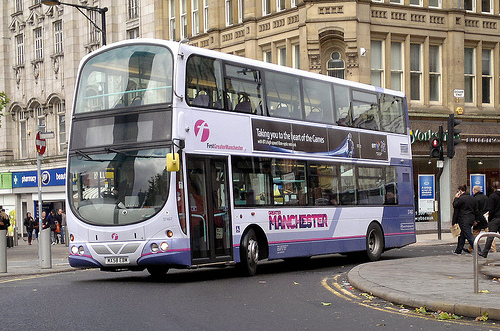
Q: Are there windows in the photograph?
A: Yes, there is a window.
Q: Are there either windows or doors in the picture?
A: Yes, there is a window.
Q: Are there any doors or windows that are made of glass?
A: Yes, the window is made of glass.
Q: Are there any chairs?
A: No, there are no chairs.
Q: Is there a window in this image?
A: Yes, there is a window.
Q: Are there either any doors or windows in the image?
A: Yes, there is a window.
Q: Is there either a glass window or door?
A: Yes, there is a glass window.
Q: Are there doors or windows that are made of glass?
A: Yes, the window is made of glass.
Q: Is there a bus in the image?
A: Yes, there is a bus.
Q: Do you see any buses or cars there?
A: Yes, there is a bus.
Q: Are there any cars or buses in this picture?
A: Yes, there is a bus.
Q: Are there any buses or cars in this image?
A: Yes, there is a bus.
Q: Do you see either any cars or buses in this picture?
A: Yes, there is a bus.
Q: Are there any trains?
A: No, there are no trains.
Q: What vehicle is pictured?
A: The vehicle is a bus.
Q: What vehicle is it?
A: The vehicle is a bus.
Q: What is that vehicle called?
A: This is a bus.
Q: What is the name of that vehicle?
A: This is a bus.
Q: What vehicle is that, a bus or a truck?
A: This is a bus.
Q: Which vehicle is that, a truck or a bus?
A: This is a bus.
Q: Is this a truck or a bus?
A: This is a bus.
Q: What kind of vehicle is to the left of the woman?
A: The vehicle is a bus.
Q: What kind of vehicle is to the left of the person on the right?
A: The vehicle is a bus.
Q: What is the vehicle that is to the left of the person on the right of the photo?
A: The vehicle is a bus.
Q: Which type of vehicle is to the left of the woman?
A: The vehicle is a bus.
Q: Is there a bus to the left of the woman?
A: Yes, there is a bus to the left of the woman.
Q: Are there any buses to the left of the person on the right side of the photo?
A: Yes, there is a bus to the left of the woman.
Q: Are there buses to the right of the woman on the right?
A: No, the bus is to the left of the woman.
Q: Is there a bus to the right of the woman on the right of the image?
A: No, the bus is to the left of the woman.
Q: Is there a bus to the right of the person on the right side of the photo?
A: No, the bus is to the left of the woman.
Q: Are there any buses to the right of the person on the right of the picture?
A: No, the bus is to the left of the woman.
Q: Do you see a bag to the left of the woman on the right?
A: No, there is a bus to the left of the woman.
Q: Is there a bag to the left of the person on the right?
A: No, there is a bus to the left of the woman.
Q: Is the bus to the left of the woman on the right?
A: Yes, the bus is to the left of the woman.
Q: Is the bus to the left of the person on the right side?
A: Yes, the bus is to the left of the woman.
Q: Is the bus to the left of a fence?
A: No, the bus is to the left of the woman.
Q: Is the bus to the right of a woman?
A: No, the bus is to the left of a woman.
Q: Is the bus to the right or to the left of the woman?
A: The bus is to the left of the woman.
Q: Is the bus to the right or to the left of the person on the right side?
A: The bus is to the left of the woman.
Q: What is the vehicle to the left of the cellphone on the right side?
A: The vehicle is a bus.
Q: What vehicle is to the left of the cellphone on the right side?
A: The vehicle is a bus.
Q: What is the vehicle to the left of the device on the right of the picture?
A: The vehicle is a bus.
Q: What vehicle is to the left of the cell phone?
A: The vehicle is a bus.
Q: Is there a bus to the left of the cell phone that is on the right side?
A: Yes, there is a bus to the left of the cell phone.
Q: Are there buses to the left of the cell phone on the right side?
A: Yes, there is a bus to the left of the cell phone.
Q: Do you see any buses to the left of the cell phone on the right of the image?
A: Yes, there is a bus to the left of the cell phone.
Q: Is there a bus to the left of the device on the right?
A: Yes, there is a bus to the left of the cell phone.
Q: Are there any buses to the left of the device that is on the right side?
A: Yes, there is a bus to the left of the cell phone.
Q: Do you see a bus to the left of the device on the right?
A: Yes, there is a bus to the left of the cell phone.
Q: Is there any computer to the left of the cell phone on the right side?
A: No, there is a bus to the left of the cellphone.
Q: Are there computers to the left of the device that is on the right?
A: No, there is a bus to the left of the cellphone.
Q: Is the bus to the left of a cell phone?
A: Yes, the bus is to the left of a cell phone.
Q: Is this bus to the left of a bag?
A: No, the bus is to the left of a cell phone.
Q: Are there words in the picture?
A: Yes, there are words.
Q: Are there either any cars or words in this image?
A: Yes, there are words.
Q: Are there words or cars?
A: Yes, there are words.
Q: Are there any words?
A: Yes, there are words.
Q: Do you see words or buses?
A: Yes, there are words.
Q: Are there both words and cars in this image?
A: No, there are words but no cars.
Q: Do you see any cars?
A: No, there are no cars.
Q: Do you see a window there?
A: Yes, there is a window.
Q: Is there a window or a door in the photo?
A: Yes, there is a window.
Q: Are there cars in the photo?
A: No, there are no cars.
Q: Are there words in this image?
A: Yes, there are words.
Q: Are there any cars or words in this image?
A: Yes, there are words.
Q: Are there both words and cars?
A: No, there are words but no cars.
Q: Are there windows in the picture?
A: Yes, there is a window.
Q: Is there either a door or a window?
A: Yes, there is a window.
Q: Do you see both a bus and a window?
A: Yes, there are both a window and a bus.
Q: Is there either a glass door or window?
A: Yes, there is a glass window.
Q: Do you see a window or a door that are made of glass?
A: Yes, the window is made of glass.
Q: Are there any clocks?
A: No, there are no clocks.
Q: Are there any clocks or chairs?
A: No, there are no clocks or chairs.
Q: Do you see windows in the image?
A: Yes, there is a window.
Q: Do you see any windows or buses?
A: Yes, there is a window.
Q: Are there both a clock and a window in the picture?
A: No, there is a window but no clocks.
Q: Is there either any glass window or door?
A: Yes, there is a glass window.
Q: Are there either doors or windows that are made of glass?
A: Yes, the window is made of glass.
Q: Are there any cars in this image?
A: No, there are no cars.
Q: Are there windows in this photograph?
A: Yes, there is a window.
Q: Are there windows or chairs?
A: Yes, there is a window.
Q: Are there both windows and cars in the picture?
A: No, there is a window but no cars.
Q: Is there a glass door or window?
A: Yes, there is a glass window.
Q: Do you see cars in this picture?
A: No, there are no cars.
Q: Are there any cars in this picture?
A: No, there are no cars.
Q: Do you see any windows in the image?
A: Yes, there is a window.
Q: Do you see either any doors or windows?
A: Yes, there is a window.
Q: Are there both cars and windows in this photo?
A: No, there is a window but no cars.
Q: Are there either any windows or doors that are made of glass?
A: Yes, the window is made of glass.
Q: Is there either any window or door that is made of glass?
A: Yes, the window is made of glass.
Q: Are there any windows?
A: Yes, there is a window.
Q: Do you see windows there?
A: Yes, there is a window.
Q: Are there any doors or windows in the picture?
A: Yes, there is a window.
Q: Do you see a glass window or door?
A: Yes, there is a glass window.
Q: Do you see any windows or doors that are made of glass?
A: Yes, the window is made of glass.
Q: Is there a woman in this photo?
A: Yes, there is a woman.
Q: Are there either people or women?
A: Yes, there is a woman.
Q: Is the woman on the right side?
A: Yes, the woman is on the right of the image.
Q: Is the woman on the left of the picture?
A: No, the woman is on the right of the image.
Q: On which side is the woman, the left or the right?
A: The woman is on the right of the image.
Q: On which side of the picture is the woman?
A: The woman is on the right of the image.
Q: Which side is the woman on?
A: The woman is on the right of the image.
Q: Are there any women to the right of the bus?
A: Yes, there is a woman to the right of the bus.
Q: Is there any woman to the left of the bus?
A: No, the woman is to the right of the bus.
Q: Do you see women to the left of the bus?
A: No, the woman is to the right of the bus.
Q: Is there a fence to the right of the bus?
A: No, there is a woman to the right of the bus.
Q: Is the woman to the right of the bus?
A: Yes, the woman is to the right of the bus.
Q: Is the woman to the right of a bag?
A: No, the woman is to the right of the bus.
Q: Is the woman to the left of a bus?
A: No, the woman is to the right of a bus.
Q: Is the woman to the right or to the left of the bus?
A: The woman is to the right of the bus.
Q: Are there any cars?
A: No, there are no cars.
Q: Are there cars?
A: No, there are no cars.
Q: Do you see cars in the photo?
A: No, there are no cars.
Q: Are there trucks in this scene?
A: No, there are no trucks.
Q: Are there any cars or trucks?
A: No, there are no trucks or cars.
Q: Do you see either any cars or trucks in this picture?
A: No, there are no trucks or cars.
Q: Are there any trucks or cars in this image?
A: No, there are no trucks or cars.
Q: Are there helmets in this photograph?
A: No, there are no helmets.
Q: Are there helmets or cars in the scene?
A: No, there are no helmets or cars.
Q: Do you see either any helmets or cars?
A: No, there are no helmets or cars.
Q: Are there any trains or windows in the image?
A: Yes, there is a window.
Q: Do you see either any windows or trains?
A: Yes, there is a window.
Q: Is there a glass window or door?
A: Yes, there is a glass window.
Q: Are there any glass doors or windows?
A: Yes, there is a glass window.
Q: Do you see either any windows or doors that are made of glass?
A: Yes, the window is made of glass.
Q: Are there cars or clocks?
A: No, there are no cars or clocks.